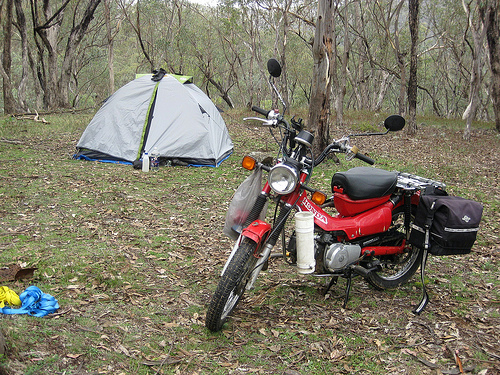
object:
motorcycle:
[205, 58, 484, 331]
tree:
[38, 0, 98, 113]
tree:
[101, 0, 124, 95]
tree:
[141, 0, 187, 74]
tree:
[218, 0, 246, 94]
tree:
[241, 0, 259, 107]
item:
[0, 283, 22, 309]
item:
[20, 284, 60, 317]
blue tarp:
[70, 153, 133, 165]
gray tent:
[70, 72, 235, 166]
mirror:
[383, 114, 405, 131]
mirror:
[267, 58, 283, 78]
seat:
[331, 166, 397, 200]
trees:
[69, 23, 107, 109]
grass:
[1, 120, 499, 373]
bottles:
[292, 211, 316, 274]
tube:
[294, 210, 316, 275]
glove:
[150, 68, 167, 82]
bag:
[406, 193, 484, 256]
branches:
[12, 108, 50, 125]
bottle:
[140, 152, 150, 172]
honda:
[301, 197, 328, 224]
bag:
[223, 166, 264, 240]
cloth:
[107, 100, 137, 142]